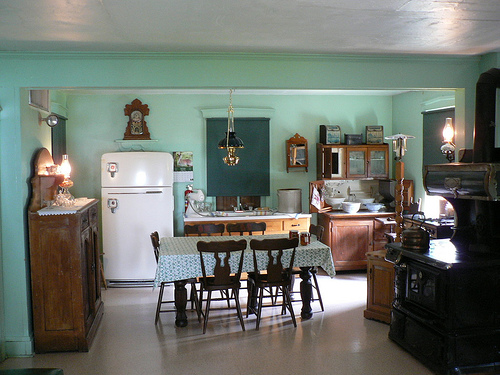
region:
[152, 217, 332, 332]
A dining room table set.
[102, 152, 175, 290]
A white refrigerator.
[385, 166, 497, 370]
A large black stove.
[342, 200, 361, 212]
A white bowl.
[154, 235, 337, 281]
A white table cloth with a design.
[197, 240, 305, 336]
Brown wooden kitchen chairs.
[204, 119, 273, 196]
A green window shade.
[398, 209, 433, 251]
A teakettle.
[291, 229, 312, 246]
Jars with white lids.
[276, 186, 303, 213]
A large silver pot.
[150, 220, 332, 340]
a small dining room table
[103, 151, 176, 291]
an old model refrigerator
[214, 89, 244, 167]
a lantern hanging above table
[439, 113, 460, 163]
a lit lamp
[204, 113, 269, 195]
a dark window shade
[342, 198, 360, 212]
white bowl on cherry wood counter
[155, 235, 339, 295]
a white tablecloth with blue dots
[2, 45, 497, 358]
light blue painted walls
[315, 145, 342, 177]
an open cabinet door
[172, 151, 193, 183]
a calender next to refrigerator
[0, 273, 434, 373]
white linoleum kitchen floor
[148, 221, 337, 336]
dining table and six wooden chairs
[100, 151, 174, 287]
a white refrigerator and freezer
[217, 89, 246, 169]
a lantern light fixture hanging from ceiling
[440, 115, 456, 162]
a kerosene lantern on top of stove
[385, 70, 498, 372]
old fashioned black wood burning stove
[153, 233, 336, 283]
white patterned table cloth on table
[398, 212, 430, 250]
copper tea kettle on top of stove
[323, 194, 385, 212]
white bowls on a sideboard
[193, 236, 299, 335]
two dark brown wooden chairs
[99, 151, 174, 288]
a white fridge in a kitchen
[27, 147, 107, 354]
a wooden cabinet in a kitchen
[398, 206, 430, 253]
a kettle on black old fashion stove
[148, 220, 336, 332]
a table with six chairs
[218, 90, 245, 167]
a gold and black chandelier hanging from the ceiling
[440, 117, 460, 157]
an oil lamp in a kitchen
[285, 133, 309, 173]
a wood framed mirror in a kitchen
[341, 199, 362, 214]
a white bowl on a shelf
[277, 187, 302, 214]
a metal pot on a counter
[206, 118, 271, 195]
green blinds on a window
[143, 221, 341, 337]
Kitchen table with tablecloth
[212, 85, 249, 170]
Light fixture hanging from the ceiling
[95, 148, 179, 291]
White fridge and freezer next to the wall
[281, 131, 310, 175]
Decorative wooden mirror hanging on the wall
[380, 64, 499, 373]
Antique black wood cook stove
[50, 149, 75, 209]
Oil lamp with orange oil on cabinet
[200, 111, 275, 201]
partially closed dark green window blind in the center of the room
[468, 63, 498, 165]
Pipe connected to the stove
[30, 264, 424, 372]
Linoleum floor covering on the kitchen floor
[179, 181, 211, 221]
White blender on the counter next to the sink